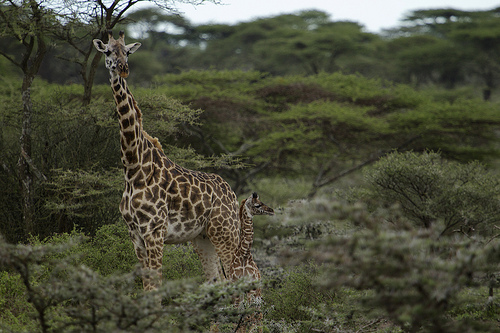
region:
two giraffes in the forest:
[82, 21, 277, 296]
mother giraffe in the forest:
[91, 28, 232, 272]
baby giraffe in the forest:
[225, 184, 285, 309]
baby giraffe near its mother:
[220, 187, 294, 308]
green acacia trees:
[197, 61, 429, 156]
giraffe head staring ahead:
[85, 24, 147, 86]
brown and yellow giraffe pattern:
[142, 168, 199, 220]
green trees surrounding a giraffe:
[280, 202, 451, 302]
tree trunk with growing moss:
[8, 25, 49, 243]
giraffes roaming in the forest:
[75, 17, 287, 304]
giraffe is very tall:
[82, 31, 139, 90]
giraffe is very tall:
[102, 39, 177, 116]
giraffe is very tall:
[82, 40, 217, 248]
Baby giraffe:
[234, 191, 274, 325]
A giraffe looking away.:
[91, 31, 241, 301]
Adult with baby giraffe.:
[89, 23, 278, 331]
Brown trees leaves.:
[251, 84, 328, 105]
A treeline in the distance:
[176, 14, 498, 156]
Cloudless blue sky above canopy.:
[226, 0, 397, 11]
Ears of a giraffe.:
[100, 25, 125, 40]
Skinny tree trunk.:
[15, 60, 35, 235]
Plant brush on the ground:
[0, 275, 400, 330]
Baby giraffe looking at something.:
[227, 190, 277, 317]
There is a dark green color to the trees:
[316, 87, 341, 133]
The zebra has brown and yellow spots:
[154, 175, 191, 227]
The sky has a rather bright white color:
[381, 5, 386, 17]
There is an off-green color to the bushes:
[351, 232, 366, 249]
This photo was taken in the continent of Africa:
[71, 23, 429, 304]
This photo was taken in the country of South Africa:
[80, 24, 366, 321]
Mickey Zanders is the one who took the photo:
[75, 40, 418, 315]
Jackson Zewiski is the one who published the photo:
[76, 20, 423, 321]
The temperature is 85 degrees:
[78, 25, 343, 320]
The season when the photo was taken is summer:
[55, 15, 348, 309]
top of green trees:
[203, 17, 245, 40]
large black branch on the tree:
[299, 170, 344, 212]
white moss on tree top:
[278, 190, 383, 245]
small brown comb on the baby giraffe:
[237, 195, 252, 232]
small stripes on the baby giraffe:
[254, 205, 280, 218]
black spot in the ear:
[81, 35, 108, 60]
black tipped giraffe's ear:
[101, 19, 126, 42]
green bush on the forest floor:
[152, 254, 194, 277]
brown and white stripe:
[137, 180, 172, 211]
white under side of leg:
[183, 240, 213, 267]